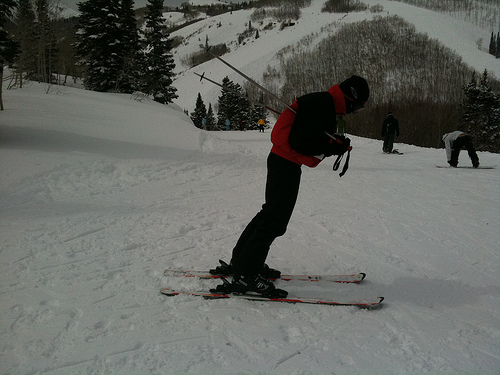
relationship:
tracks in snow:
[1, 166, 162, 374] [1, 128, 498, 374]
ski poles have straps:
[197, 37, 339, 156] [335, 141, 352, 176]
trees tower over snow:
[77, 1, 180, 105] [1, 2, 500, 374]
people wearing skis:
[228, 76, 370, 297] [163, 270, 387, 307]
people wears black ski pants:
[228, 76, 370, 297] [234, 155, 303, 287]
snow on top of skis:
[1, 128, 498, 374] [163, 270, 387, 307]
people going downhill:
[228, 76, 370, 297] [1, 71, 500, 175]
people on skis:
[228, 76, 370, 297] [163, 270, 387, 307]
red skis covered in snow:
[163, 270, 387, 307] [1, 128, 498, 374]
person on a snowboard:
[440, 128, 484, 169] [435, 163, 499, 172]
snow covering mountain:
[1, 2, 500, 374] [169, 8, 500, 142]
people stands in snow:
[228, 76, 370, 297] [1, 128, 498, 374]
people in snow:
[258, 76, 484, 170] [1, 128, 498, 374]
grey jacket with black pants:
[441, 130, 467, 161] [451, 136, 483, 170]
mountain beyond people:
[169, 8, 500, 142] [258, 76, 484, 170]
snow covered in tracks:
[1, 128, 498, 374] [1, 166, 162, 374]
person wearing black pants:
[440, 128, 484, 169] [451, 136, 483, 170]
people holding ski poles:
[228, 76, 370, 297] [197, 37, 339, 156]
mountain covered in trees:
[169, 8, 500, 142] [269, 17, 485, 138]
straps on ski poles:
[335, 141, 352, 176] [197, 37, 339, 156]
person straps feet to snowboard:
[440, 128, 484, 169] [435, 163, 499, 172]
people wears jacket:
[228, 76, 370, 297] [270, 78, 348, 168]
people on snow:
[258, 76, 484, 170] [1, 128, 498, 374]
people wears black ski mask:
[228, 76, 370, 297] [339, 76, 372, 111]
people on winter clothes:
[228, 76, 370, 297] [209, 70, 372, 297]